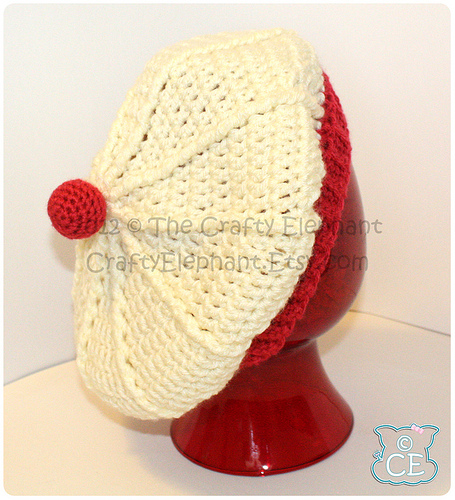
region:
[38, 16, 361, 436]
a cap of yarn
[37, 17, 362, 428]
a handmade cap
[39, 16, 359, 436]
cap is color white and red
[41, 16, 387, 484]
a cap is display on a model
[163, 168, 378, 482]
model is red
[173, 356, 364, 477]
base of model is wide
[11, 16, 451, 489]
model is on a white table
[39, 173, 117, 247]
a red pom pom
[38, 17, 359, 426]
cap knit with crochet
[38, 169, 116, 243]
pom pom is small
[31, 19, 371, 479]
slouchy cap on a mannequin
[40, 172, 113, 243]
red pom pom on top of the hat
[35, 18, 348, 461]
red and white crocheted hat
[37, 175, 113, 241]
crocheted ball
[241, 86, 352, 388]
red border on the bottom of the hat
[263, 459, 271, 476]
light glare on the mannequin's neck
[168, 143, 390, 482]
red mannequin head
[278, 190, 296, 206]
small slit in the crochet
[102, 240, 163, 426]
raised row of crochet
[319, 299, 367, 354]
shadow from the mannequin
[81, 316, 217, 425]
This is a woven head cover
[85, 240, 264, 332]
This is a woven head cover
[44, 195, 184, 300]
This is a woven head cover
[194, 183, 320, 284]
This is a woven head cover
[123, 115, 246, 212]
This is a woven head cover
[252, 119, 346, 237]
This is a woven head cover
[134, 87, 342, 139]
This is a woven head cover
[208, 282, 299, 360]
This is a woven head cover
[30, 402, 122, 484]
The counter top is off white.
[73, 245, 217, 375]
Part of the hat is white.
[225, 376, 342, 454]
The hat stand is transparent red.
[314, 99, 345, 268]
The trim of the hat is red.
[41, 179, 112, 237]
The top of the hat is red.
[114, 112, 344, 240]
This hat is made of yarn.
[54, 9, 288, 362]
The hat has been knitted.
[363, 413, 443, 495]
The photo containers a watermark.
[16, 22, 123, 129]
The background of wall is light gray.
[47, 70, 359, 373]
The hat is handmade.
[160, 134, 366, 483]
THIS IS A MANNEQUIN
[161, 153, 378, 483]
THE MANNEQUIN IS RED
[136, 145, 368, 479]
THE MANNEQUIN IS WEARING A HAT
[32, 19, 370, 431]
THE HAT IS CROCHET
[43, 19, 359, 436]
THE HAT IS WHITE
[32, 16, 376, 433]
THIS IS A HAT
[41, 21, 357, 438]
THE HAT HAS RED TRIM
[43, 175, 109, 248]
THE HAT HAS A BALL ON IT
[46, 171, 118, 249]
THE BALL IS RED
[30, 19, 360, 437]
THE HAT IS ON DISPLAY